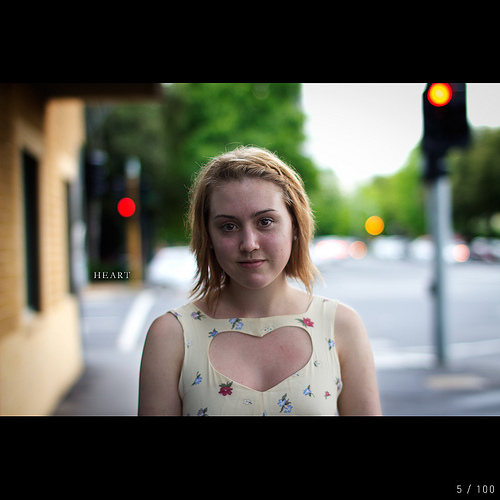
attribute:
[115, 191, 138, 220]
light — blurred, red, behind her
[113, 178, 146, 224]
traffic light — blurry, red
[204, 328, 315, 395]
pattern — heart shaped, a heart, cut out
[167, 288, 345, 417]
woman's top — sleeveless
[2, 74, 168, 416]
building — made from bricks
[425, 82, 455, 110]
light — blurred, yellow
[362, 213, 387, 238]
light — blurred, yellow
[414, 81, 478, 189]
traffic light — blurry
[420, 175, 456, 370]
pole — blurry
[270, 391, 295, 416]
flower pattern — blue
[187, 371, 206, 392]
flower pattern — blue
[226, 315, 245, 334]
flower pattern — blue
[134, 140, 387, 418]
woman — looking, white, blonde, standing outside, young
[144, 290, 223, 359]
woman's shoulder — bare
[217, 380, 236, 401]
flower — red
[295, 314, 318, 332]
flower — red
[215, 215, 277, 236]
eyes — brown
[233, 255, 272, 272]
mouth — closed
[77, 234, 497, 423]
street — blurry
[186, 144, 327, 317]
hair — strawberry blonde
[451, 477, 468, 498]
number 5 — depicted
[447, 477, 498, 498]
numbers — depicted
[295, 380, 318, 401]
flower pattern — blue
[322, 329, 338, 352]
flower pattern — blue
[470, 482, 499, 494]
number one hundred — depicted